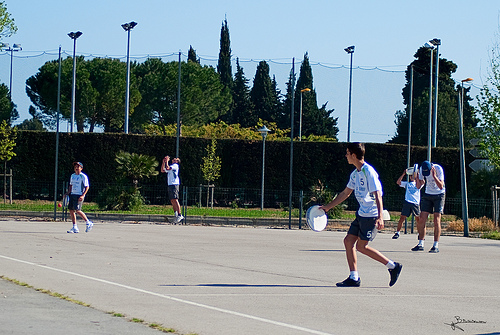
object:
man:
[318, 141, 403, 288]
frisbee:
[305, 205, 327, 232]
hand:
[316, 204, 330, 214]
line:
[0, 254, 330, 335]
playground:
[0, 209, 499, 333]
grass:
[1, 198, 498, 221]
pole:
[2, 52, 18, 132]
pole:
[51, 48, 67, 219]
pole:
[120, 21, 137, 134]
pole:
[175, 52, 182, 159]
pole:
[287, 56, 296, 228]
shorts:
[345, 211, 381, 242]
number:
[365, 230, 373, 240]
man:
[411, 160, 446, 254]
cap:
[421, 160, 433, 177]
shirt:
[343, 163, 386, 218]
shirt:
[416, 164, 447, 195]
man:
[160, 154, 185, 226]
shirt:
[164, 163, 179, 186]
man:
[63, 162, 94, 235]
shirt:
[67, 173, 90, 195]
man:
[392, 166, 426, 241]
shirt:
[399, 179, 426, 205]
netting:
[0, 52, 499, 149]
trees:
[198, 131, 224, 207]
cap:
[73, 161, 84, 168]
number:
[358, 177, 365, 186]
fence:
[0, 186, 499, 234]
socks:
[349, 269, 359, 281]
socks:
[432, 240, 440, 249]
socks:
[72, 223, 79, 229]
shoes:
[64, 226, 81, 235]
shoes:
[174, 215, 185, 224]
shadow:
[160, 283, 337, 289]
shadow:
[299, 249, 417, 254]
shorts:
[67, 194, 82, 211]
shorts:
[167, 185, 180, 200]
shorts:
[400, 201, 421, 218]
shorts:
[420, 192, 445, 215]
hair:
[347, 140, 365, 160]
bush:
[115, 149, 159, 194]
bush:
[304, 179, 348, 219]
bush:
[95, 184, 144, 211]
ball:
[58, 202, 63, 208]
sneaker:
[336, 275, 361, 287]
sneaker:
[387, 262, 403, 287]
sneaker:
[390, 233, 400, 239]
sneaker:
[409, 245, 424, 252]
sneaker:
[428, 246, 440, 254]